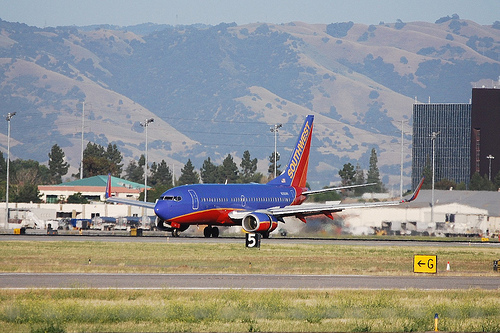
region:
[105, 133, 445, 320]
an airplane on the ground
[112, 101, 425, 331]
a plane on the ground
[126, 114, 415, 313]
a large plane on the ground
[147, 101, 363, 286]
a large airplane on the ground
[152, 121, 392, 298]
a passenger plane on the ground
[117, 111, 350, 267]
a passenger airplane on the ground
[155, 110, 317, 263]
a large passenger plane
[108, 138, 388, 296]
a large passenger airplane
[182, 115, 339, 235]
a blue airplane on the ground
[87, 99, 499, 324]
a blue plane on the ground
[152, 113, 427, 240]
Blue and red airplane on landing strip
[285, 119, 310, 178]
Name of airline services on wing of airplane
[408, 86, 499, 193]
Office buildings near airport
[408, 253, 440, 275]
Yellow sign on ground beside landing strip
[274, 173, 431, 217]
Wings on the airplane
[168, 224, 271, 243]
Wheels on the airplane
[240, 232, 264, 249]
Black number sign on ground beside airplane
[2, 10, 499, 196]
Large hills in background of airport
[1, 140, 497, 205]
Trees surrounding the airport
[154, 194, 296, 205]
Windows on side of airplane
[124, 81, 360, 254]
Red and blue plane on the runway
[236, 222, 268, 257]
Small black and white sign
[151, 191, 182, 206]
Large window on an airplane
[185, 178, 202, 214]
Large door of an airplane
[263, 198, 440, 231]
Large wing on a plane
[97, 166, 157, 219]
Large wing on a plane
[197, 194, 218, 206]
Small windows of a plane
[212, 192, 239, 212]
Small windows of a plane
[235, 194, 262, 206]
Small windows of a plane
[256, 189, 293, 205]
Small windows of a plane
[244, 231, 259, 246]
the sign with the number 5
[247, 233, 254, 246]
the number 5 on the sign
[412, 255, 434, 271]
the sign with the letter G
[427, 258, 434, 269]
the letter G on the sign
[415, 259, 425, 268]
the arrow on the sign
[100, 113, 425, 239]
the airplane on the tarmac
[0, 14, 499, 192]
the mountain behind the airplane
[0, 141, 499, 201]
the trees behind the airplane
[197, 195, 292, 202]
the windows on the airplane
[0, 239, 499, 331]
the grass near the tarmac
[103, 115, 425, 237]
A passenger jet on the runway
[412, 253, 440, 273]
A yellow sign by the runway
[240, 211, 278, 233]
A jet engine on the plane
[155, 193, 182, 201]
The plane's cockpit windows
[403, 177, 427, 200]
A red wing tip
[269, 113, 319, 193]
The plane's blue orange and red tail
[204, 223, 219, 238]
Wheels under the plane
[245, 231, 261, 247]
A black sign with a white number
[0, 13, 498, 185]
Large hills in the background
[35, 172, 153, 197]
A building with a green roof